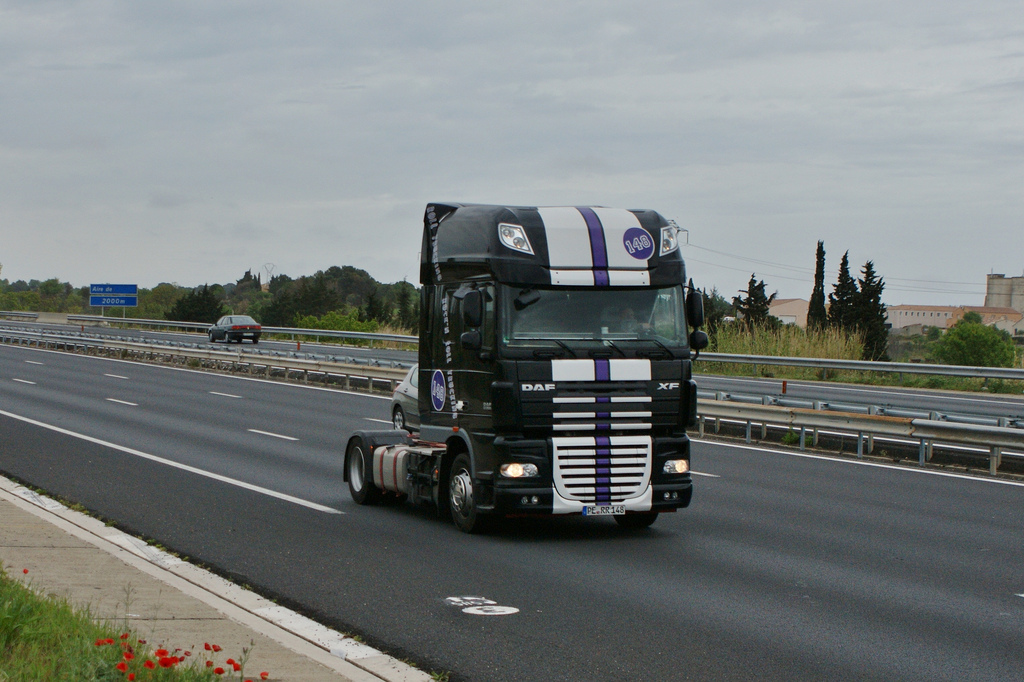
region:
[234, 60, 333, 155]
a view of clouds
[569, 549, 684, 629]
a view of road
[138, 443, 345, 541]
lines in the road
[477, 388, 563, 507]
a view of lights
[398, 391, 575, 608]
a view of wheel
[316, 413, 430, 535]
a view of tire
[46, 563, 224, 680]
a view of grass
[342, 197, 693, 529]
A mostly black semi cab with white and purple on the front.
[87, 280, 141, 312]
Two blue signs on top of each other.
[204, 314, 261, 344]
Black car driving away.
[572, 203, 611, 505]
Purple stripe going down a semi.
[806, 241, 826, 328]
The tallest thinnest tree.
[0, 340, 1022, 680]
Grey paved road a semi is driving on.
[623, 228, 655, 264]
Purple circle on top of a semi.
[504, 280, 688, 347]
Windshield on a semi cab.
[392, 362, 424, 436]
Grey car behind a semi.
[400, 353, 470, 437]
blue and white logo on side of truck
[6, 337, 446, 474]
dashed white lines on highway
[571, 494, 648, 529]
license plate on front of truck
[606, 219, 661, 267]
blue and white logo on top of truck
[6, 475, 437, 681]
sloped cement ditch on side of road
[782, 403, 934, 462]
rusted portion of center guardrail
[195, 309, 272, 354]
black compact car on road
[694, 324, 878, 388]
tall grasses on side of road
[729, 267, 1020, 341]
building with a tall tower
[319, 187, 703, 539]
semi truck with no load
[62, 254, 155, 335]
blue highway sign with white lettering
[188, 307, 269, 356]
black car headed toward sign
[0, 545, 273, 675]
red wildflowers on side of road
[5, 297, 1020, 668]
six land highway with traffic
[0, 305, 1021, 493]
guardrail down the center of highway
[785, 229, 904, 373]
three pine trees in front of building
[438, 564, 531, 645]
rounded white marking on the road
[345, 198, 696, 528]
Truck has a purple stripe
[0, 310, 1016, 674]
car on the road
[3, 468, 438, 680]
red flowers beside sidewalk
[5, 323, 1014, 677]
white lines on the road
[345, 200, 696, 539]
Truck has headlights on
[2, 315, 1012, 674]
guard rails on road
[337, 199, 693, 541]
Truck is black, white, and purple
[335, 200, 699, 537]
License plate on front of truck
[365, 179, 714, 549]
black white and purple truck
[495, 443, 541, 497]
white head light on moving truck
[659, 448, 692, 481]
white head light on moving truck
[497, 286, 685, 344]
windshield on moving truck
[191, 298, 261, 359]
black car on highway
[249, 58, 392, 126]
white clouds in blue sky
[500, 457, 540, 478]
The left headlight of the truck.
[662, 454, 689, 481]
The right headlight of the truck.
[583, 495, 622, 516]
The front license plate of the truck.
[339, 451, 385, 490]
The back tire of the truck.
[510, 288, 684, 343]
The front window of the truck.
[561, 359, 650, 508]
The front grill of the truck.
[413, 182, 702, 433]
The cab of the truck on the road.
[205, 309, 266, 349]
The car driving down the road.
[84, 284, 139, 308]
The blue highway sign in front of the car.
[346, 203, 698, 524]
black truck traveling down road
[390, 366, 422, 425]
silver vehicle traveling down road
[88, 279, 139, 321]
blue sign posted near guard rail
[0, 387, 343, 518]
white solid line painted on the road